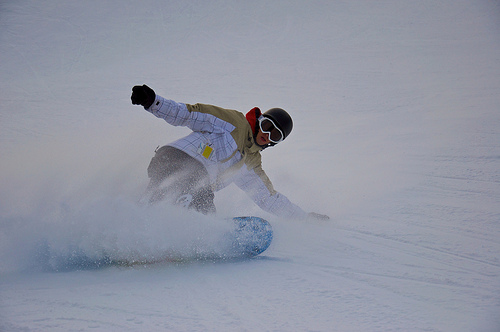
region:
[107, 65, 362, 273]
A snowboarder coming down a slope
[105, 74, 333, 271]
snowboarder doing trick on snow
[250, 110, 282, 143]
goggles on snowboarder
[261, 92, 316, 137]
black helmet on boarder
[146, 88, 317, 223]
white jacket on snowboarder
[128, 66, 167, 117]
black glove on snowboarder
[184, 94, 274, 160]
yellow on man's jacket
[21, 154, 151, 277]
snow spraying up in the air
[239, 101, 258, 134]
red hood of man's jacket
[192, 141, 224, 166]
yellow tag on jacket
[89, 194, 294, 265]
blue snowboard under boarder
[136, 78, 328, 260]
man is on a snowboar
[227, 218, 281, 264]
tip of the snowboard is visibile through the snow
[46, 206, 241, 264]
snowboard is hidden behind the snow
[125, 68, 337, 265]
snowboarder is leaning on his left side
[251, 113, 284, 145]
skii glasses on the person's face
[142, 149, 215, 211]
the boarder is wearing black pants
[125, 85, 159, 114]
black glove on the boarder's right hand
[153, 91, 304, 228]
person is wearing a white and dark yellow jacket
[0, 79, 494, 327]
fresh snow on the ground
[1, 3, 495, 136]
sky is blurred with white snow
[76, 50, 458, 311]
a man in the ice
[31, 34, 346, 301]
a man in the snow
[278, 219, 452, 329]
a view of snow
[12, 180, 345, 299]
ice raising up to air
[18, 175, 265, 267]
snow raising up to air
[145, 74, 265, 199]
a man wearing jacket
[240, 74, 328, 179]
a man wearing cap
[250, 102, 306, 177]
a man wearing spects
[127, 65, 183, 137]
a man wearing gloves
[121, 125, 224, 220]
a man wearing pants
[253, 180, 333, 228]
hand of the person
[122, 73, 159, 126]
gloves of the person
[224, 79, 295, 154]
a person wearing cap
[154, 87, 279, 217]
a person wearing jacket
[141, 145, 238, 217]
a person wearing pants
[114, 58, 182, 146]
a person wearing gloves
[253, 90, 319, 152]
a person wearing spects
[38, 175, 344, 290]
a skate board in ice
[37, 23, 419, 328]
a person diving in ice